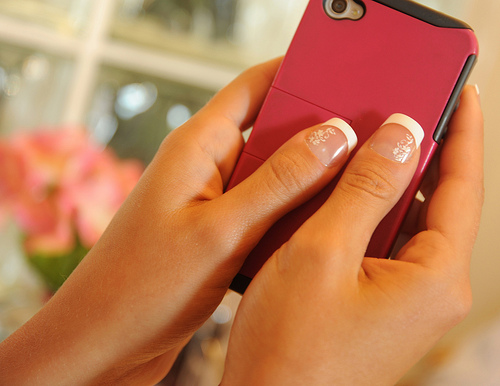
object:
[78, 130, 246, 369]
palm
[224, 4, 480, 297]
phone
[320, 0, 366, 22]
camara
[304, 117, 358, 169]
nail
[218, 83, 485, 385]
hand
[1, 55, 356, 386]
hand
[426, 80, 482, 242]
finger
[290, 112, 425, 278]
thumb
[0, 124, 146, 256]
flowers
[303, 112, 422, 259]
finger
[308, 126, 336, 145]
drawing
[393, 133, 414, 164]
drawing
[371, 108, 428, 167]
nail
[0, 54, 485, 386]
person